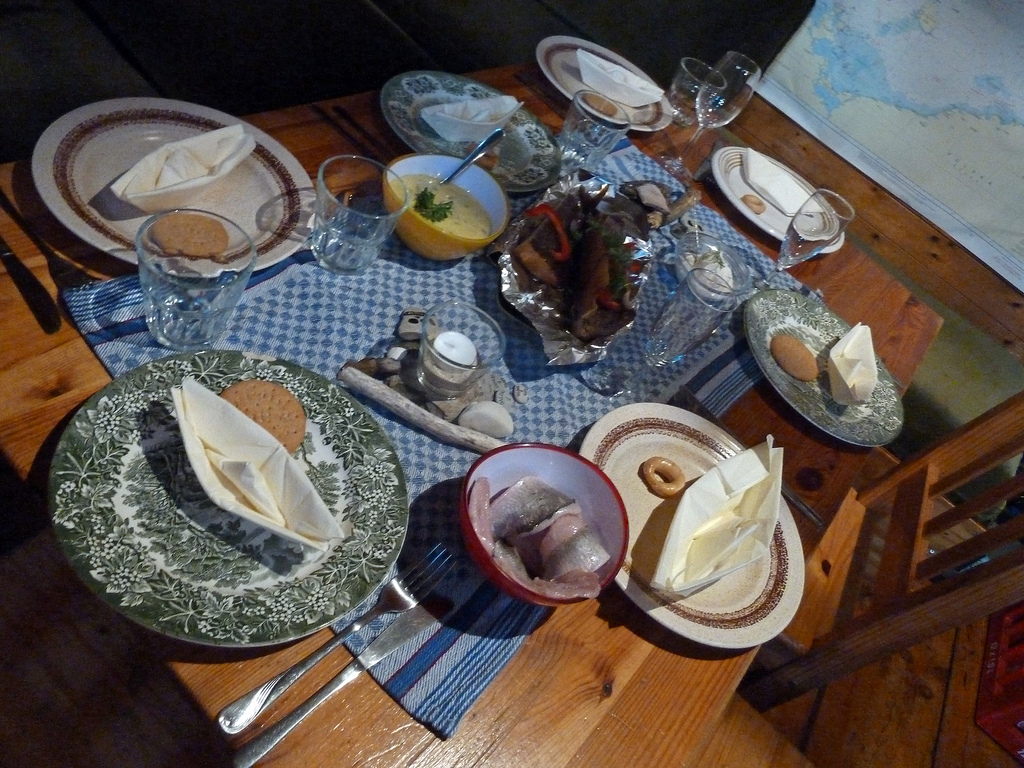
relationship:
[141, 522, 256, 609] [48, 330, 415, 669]
design on plate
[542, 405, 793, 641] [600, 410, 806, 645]
food on plate